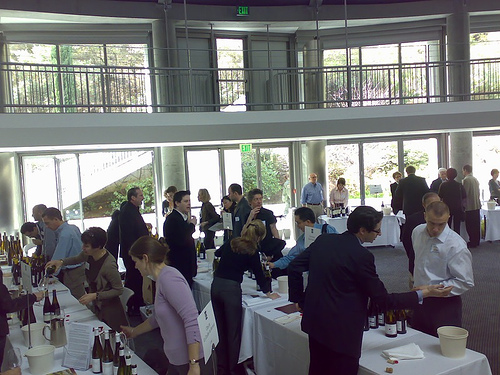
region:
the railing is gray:
[202, 60, 277, 99]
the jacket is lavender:
[168, 287, 185, 323]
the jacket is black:
[322, 252, 343, 298]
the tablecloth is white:
[265, 335, 292, 357]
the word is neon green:
[229, 2, 259, 22]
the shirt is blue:
[308, 190, 323, 200]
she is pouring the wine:
[34, 252, 68, 294]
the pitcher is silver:
[43, 315, 82, 351]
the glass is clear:
[116, 330, 143, 363]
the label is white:
[381, 317, 408, 351]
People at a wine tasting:
[0, 145, 489, 358]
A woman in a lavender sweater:
[112, 236, 202, 373]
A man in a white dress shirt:
[388, 198, 487, 308]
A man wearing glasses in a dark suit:
[300, 206, 417, 365]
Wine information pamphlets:
[61, 323, 106, 373]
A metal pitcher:
[37, 312, 80, 355]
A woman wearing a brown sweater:
[40, 223, 140, 325]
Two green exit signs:
[220, 5, 262, 163]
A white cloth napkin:
[378, 334, 442, 371]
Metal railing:
[5, 49, 499, 129]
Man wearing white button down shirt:
[412, 202, 477, 327]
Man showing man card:
[287, 207, 457, 374]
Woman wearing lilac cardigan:
[115, 232, 212, 374]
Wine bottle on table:
[87, 322, 105, 371]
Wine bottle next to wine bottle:
[92, 320, 102, 373]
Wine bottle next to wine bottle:
[100, 325, 113, 373]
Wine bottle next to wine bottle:
[40, 285, 55, 325]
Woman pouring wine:
[43, 225, 135, 336]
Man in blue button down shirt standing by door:
[298, 167, 323, 217]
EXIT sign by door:
[230, 140, 260, 157]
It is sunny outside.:
[32, 47, 435, 204]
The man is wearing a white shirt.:
[417, 230, 474, 288]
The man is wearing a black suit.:
[299, 220, 376, 368]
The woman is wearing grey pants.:
[211, 275, 247, 368]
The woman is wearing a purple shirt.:
[152, 270, 198, 355]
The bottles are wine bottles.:
[369, 295, 416, 344]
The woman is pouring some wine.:
[40, 259, 64, 294]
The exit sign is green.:
[230, 5, 261, 22]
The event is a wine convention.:
[13, 22, 470, 348]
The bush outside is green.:
[245, 160, 284, 190]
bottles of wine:
[80, 319, 159, 372]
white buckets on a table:
[428, 320, 480, 373]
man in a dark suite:
[266, 194, 407, 374]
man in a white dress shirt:
[402, 197, 487, 336]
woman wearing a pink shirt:
[118, 232, 229, 372]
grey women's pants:
[208, 268, 255, 374]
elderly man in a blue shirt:
[301, 169, 325, 225]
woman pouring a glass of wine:
[31, 220, 133, 341]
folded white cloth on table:
[376, 334, 431, 372]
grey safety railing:
[53, 51, 218, 122]